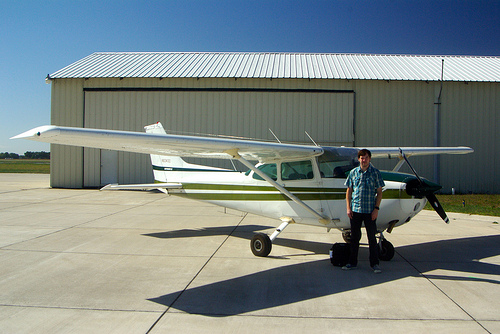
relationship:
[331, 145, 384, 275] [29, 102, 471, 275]
man in front of plane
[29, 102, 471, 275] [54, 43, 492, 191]
plane near hangar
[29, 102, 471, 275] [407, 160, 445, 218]
plane has propeller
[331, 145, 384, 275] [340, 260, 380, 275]
man has shoes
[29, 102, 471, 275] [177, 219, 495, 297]
plane has shadow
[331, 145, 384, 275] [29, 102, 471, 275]
man near plane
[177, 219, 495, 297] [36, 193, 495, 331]
shadow cast on ground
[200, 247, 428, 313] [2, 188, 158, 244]
square part of tarmac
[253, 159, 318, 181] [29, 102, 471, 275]
window on side of plane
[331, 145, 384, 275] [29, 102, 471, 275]
man next to plane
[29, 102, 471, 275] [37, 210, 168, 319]
plane sitting on cement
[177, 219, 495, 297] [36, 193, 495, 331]
shadow stretches on ground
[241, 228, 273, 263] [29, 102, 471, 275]
wheel on side of plane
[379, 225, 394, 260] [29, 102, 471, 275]
wheel on left of plane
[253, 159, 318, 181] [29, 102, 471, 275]
window on back of plane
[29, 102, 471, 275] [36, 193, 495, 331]
plane on ground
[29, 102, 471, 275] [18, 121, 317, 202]
plane has wing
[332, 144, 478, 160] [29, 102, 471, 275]
wing on side of plane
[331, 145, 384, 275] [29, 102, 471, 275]
man outside plane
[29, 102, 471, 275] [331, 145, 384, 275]
plane beside man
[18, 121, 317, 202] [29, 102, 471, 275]
wing on side of plane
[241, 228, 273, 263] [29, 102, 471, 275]
wheel under plane